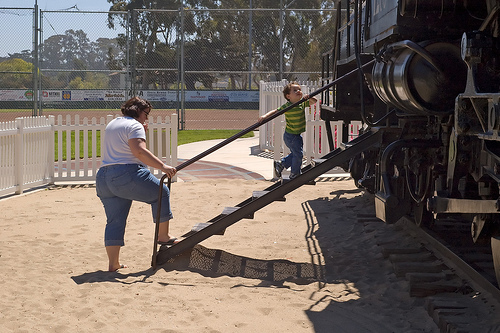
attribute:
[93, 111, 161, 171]
white shirt — white 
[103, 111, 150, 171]
white shirt — white 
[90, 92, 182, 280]
woman — blue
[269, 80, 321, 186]
boy — yougn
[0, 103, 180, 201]
fence — white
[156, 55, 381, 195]
handrail — metal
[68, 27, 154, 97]
fence — large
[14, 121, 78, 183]
fence — white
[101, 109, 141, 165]
shirt — white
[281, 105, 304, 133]
shirt — striped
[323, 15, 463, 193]
train — black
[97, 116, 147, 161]
shirt — white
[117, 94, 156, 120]
hair — brown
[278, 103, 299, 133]
shirt — striped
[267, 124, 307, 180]
pants — blue